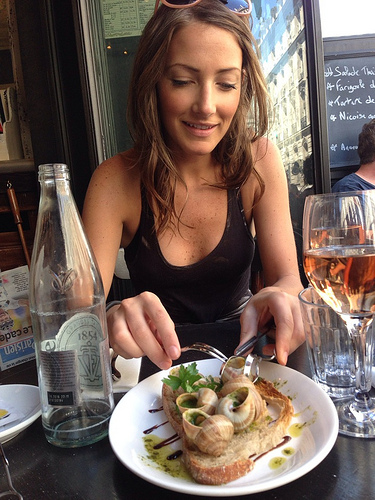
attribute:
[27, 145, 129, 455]
bottle — empty, glass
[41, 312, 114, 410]
label — 1854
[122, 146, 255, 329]
top — black, tank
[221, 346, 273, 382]
opener — silver, shell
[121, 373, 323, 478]
bread — peice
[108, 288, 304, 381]
hands — both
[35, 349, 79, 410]
label — silver, black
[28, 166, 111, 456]
bottle — empty, glass, clear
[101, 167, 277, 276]
tank top — black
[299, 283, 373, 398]
glass — empty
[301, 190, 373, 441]
wine glass — tall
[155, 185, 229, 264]
freckled body — light skinned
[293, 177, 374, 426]
glass — wine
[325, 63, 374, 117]
menu — special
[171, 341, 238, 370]
fork — silver, metal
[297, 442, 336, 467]
plate — round, white, ceramic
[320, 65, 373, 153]
writing — chalk, white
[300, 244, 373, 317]
liquid — amber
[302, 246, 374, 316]
beverage — peach colored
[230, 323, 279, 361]
handle — black